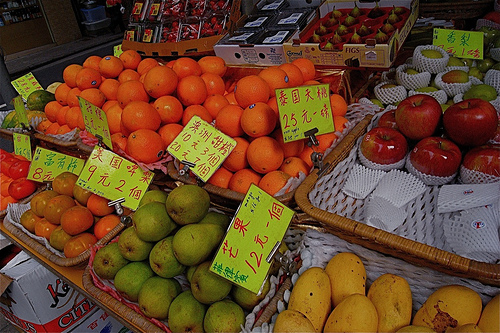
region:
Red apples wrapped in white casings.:
[355, 83, 499, 191]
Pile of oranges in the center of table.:
[42, 46, 359, 191]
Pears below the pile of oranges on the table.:
[122, 178, 254, 330]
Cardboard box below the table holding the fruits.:
[1, 258, 92, 331]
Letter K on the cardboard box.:
[36, 275, 74, 311]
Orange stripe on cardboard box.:
[0, 301, 102, 326]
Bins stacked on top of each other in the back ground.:
[78, 3, 116, 42]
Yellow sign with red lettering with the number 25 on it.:
[278, 85, 340, 147]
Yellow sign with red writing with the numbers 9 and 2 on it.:
[76, 145, 153, 214]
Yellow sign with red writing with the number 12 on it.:
[215, 180, 300, 297]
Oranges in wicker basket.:
[170, 54, 358, 189]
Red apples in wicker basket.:
[293, 89, 497, 260]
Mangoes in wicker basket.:
[278, 242, 462, 332]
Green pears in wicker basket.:
[86, 183, 254, 332]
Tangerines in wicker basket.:
[25, 187, 121, 266]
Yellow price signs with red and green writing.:
[211, 185, 296, 297]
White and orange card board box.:
[1, 258, 112, 331]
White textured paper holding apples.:
[352, 168, 498, 258]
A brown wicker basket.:
[293, 183, 499, 273]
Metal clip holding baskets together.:
[308, 148, 337, 180]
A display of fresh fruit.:
[4, 6, 494, 329]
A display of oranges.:
[53, 45, 352, 208]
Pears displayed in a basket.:
[98, 177, 279, 332]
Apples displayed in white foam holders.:
[365, 35, 497, 210]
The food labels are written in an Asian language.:
[6, 10, 491, 295]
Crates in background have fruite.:
[215, 2, 426, 72]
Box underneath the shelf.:
[1, 225, 121, 332]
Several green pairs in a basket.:
[93, 176, 283, 331]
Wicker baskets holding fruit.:
[14, 45, 491, 325]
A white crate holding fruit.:
[209, 3, 310, 65]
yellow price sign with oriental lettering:
[215, 189, 290, 291]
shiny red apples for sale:
[356, 92, 498, 177]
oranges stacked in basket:
[182, 60, 345, 200]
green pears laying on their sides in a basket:
[81, 190, 281, 332]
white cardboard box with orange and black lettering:
[0, 257, 135, 329]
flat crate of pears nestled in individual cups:
[289, 3, 419, 70]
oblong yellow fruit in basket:
[271, 254, 498, 331]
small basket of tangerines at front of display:
[6, 173, 108, 262]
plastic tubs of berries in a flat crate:
[215, 2, 315, 65]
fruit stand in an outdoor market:
[6, 0, 498, 332]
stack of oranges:
[110, 61, 187, 124]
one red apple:
[408, 133, 461, 184]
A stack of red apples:
[376, 96, 497, 186]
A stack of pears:
[126, 231, 208, 307]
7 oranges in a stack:
[111, 66, 183, 127]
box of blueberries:
[238, 10, 288, 55]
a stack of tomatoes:
[0, 152, 30, 178]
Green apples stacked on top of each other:
[419, 50, 493, 96]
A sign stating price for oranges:
[273, 83, 335, 140]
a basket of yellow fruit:
[283, 252, 398, 332]